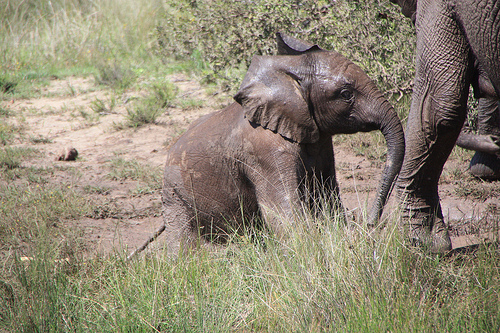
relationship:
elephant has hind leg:
[122, 30, 407, 265] [161, 197, 197, 262]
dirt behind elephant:
[9, 70, 225, 261] [122, 30, 407, 265]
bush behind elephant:
[154, 2, 421, 104] [122, 30, 407, 265]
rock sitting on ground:
[54, 145, 80, 162] [1, 1, 499, 253]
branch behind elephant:
[15, 252, 78, 265] [122, 30, 407, 265]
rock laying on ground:
[54, 145, 80, 162] [1, 1, 499, 253]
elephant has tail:
[122, 30, 407, 265] [123, 220, 169, 264]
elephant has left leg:
[390, 1, 499, 261] [466, 77, 499, 180]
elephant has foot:
[390, 1, 499, 261] [399, 213, 455, 251]